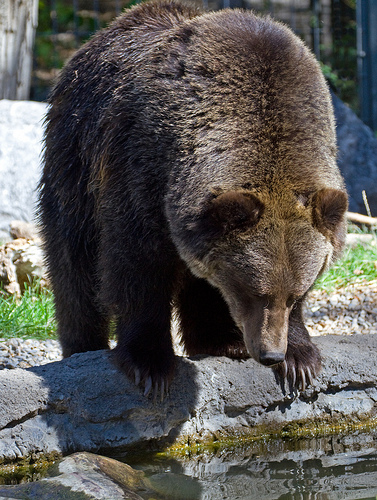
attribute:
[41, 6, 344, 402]
bear — brown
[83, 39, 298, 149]
fur — brown